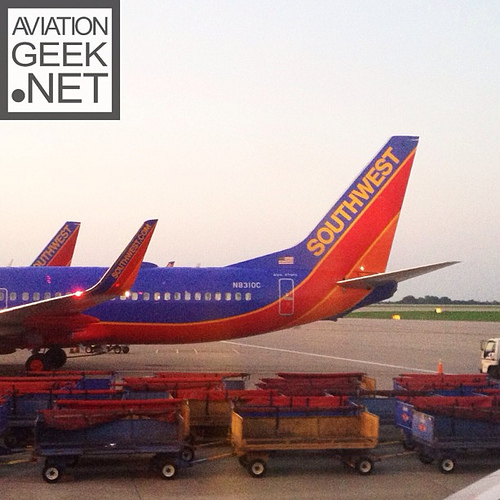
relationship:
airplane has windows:
[0, 125, 469, 367] [0, 286, 258, 304]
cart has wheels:
[230, 405, 385, 459] [236, 451, 377, 480]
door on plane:
[271, 272, 300, 320] [0, 134, 456, 367]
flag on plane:
[274, 251, 300, 269] [0, 134, 456, 367]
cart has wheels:
[408, 402, 498, 477] [417, 447, 459, 476]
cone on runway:
[434, 356, 446, 379] [1, 312, 498, 499]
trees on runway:
[349, 286, 499, 309] [1, 312, 498, 499]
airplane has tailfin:
[0, 125, 469, 367] [299, 129, 422, 274]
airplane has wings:
[0, 125, 469, 367] [0, 212, 162, 340]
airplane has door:
[0, 125, 469, 367] [271, 272, 300, 320]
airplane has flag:
[0, 125, 469, 367] [274, 251, 300, 269]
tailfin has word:
[299, 129, 422, 274] [304, 145, 404, 258]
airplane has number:
[0, 125, 469, 367] [229, 281, 264, 294]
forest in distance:
[356, 276, 500, 325] [0, 211, 499, 345]